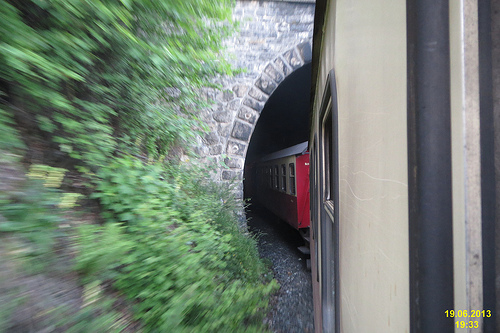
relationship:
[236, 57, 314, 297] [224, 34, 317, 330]
entrance of tunnel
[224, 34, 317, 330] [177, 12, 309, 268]
tunnel built of stones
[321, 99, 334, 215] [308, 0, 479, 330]
window built into car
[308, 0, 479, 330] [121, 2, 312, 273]
car exiting tunnel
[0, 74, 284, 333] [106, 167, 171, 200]
plants near railways grow wildly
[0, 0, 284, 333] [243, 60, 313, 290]
plants by side of tunnel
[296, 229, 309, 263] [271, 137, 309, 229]
footboard to climb into the car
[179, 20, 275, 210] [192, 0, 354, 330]
stone wall of tunnel mouth